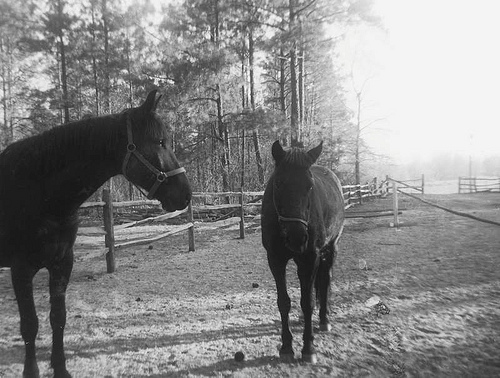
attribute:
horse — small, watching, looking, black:
[261, 139, 347, 366]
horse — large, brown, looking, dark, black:
[1, 89, 193, 377]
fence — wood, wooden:
[194, 188, 260, 242]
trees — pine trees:
[190, 2, 264, 196]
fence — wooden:
[345, 176, 428, 209]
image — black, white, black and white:
[0, 0, 499, 375]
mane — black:
[9, 106, 144, 171]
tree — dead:
[350, 69, 368, 207]